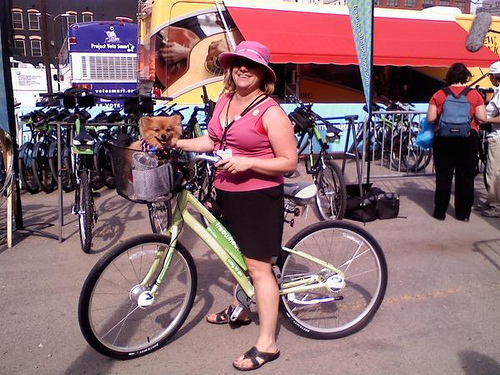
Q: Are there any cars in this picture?
A: No, there are no cars.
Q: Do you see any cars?
A: No, there are no cars.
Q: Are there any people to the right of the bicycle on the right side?
A: Yes, there is a person to the right of the bicycle.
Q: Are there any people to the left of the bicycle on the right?
A: No, the person is to the right of the bicycle.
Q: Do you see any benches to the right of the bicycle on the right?
A: No, there is a person to the right of the bicycle.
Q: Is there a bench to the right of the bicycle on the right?
A: No, there is a person to the right of the bicycle.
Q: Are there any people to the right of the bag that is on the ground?
A: Yes, there is a person to the right of the bag.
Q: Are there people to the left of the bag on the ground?
A: No, the person is to the right of the bag.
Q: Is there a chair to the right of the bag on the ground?
A: No, there is a person to the right of the bag.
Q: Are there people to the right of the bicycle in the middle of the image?
A: Yes, there is a person to the right of the bicycle.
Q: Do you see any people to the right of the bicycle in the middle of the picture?
A: Yes, there is a person to the right of the bicycle.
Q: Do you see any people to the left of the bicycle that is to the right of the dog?
A: No, the person is to the right of the bicycle.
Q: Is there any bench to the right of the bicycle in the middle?
A: No, there is a person to the right of the bicycle.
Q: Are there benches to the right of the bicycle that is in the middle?
A: No, there is a person to the right of the bicycle.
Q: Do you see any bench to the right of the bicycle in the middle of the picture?
A: No, there is a person to the right of the bicycle.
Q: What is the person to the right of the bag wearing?
A: The person is wearing a backpack.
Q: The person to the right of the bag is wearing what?
A: The person is wearing a backpack.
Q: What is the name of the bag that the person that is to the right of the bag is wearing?
A: The bag is a backpack.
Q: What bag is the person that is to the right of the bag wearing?
A: The person is wearing a backpack.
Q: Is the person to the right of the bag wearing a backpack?
A: Yes, the person is wearing a backpack.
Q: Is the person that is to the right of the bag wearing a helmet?
A: No, the person is wearing a backpack.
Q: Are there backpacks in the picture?
A: Yes, there is a backpack.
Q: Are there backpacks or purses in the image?
A: Yes, there is a backpack.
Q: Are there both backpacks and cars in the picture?
A: No, there is a backpack but no cars.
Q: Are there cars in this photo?
A: No, there are no cars.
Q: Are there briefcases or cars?
A: No, there are no cars or briefcases.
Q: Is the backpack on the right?
A: Yes, the backpack is on the right of the image.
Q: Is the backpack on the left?
A: No, the backpack is on the right of the image.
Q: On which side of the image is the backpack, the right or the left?
A: The backpack is on the right of the image.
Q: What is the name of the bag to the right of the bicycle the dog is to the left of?
A: The bag is a backpack.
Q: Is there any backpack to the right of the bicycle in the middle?
A: Yes, there is a backpack to the right of the bicycle.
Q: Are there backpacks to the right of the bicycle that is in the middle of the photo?
A: Yes, there is a backpack to the right of the bicycle.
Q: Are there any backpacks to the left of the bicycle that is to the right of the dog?
A: No, the backpack is to the right of the bicycle.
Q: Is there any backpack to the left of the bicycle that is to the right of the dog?
A: No, the backpack is to the right of the bicycle.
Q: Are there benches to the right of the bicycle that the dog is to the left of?
A: No, there is a backpack to the right of the bicycle.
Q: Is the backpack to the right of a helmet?
A: No, the backpack is to the right of a bicycle.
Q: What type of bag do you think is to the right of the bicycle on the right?
A: The bag is a backpack.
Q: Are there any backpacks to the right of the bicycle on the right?
A: Yes, there is a backpack to the right of the bicycle.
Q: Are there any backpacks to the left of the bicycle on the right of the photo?
A: No, the backpack is to the right of the bicycle.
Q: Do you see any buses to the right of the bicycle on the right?
A: No, there is a backpack to the right of the bicycle.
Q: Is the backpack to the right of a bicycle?
A: Yes, the backpack is to the right of a bicycle.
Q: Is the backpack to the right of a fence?
A: No, the backpack is to the right of a bicycle.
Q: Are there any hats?
A: Yes, there is a hat.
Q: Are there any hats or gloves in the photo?
A: Yes, there is a hat.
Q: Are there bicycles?
A: Yes, there is a bicycle.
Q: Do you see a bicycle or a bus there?
A: Yes, there is a bicycle.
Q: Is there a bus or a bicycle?
A: Yes, there is a bicycle.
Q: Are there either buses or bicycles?
A: Yes, there is a bicycle.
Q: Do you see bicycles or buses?
A: Yes, there is a bicycle.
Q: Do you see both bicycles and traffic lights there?
A: No, there is a bicycle but no traffic lights.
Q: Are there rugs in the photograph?
A: No, there are no rugs.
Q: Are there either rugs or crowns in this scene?
A: No, there are no rugs or crowns.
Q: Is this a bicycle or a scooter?
A: This is a bicycle.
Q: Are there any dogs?
A: Yes, there is a dog.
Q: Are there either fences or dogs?
A: Yes, there is a dog.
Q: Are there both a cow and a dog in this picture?
A: No, there is a dog but no cows.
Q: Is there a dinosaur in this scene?
A: No, there are no dinosaurs.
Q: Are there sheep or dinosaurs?
A: No, there are no dinosaurs or sheep.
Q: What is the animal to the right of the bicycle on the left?
A: The animal is a dog.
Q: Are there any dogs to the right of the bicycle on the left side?
A: Yes, there is a dog to the right of the bicycle.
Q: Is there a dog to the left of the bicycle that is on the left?
A: No, the dog is to the right of the bicycle.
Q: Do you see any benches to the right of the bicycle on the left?
A: No, there is a dog to the right of the bicycle.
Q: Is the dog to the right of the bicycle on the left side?
A: Yes, the dog is to the right of the bicycle.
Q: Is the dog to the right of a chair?
A: No, the dog is to the right of the bicycle.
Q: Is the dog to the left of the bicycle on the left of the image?
A: No, the dog is to the right of the bicycle.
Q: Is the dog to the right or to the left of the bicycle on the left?
A: The dog is to the right of the bicycle.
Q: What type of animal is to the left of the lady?
A: The animal is a dog.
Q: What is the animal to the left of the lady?
A: The animal is a dog.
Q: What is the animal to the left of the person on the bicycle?
A: The animal is a dog.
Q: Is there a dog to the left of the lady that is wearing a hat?
A: Yes, there is a dog to the left of the lady.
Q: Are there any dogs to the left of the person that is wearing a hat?
A: Yes, there is a dog to the left of the lady.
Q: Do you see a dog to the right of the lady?
A: No, the dog is to the left of the lady.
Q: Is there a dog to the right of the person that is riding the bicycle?
A: No, the dog is to the left of the lady.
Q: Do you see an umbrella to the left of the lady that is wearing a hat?
A: No, there is a dog to the left of the lady.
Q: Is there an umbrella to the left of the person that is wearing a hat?
A: No, there is a dog to the left of the lady.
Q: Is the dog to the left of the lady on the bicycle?
A: Yes, the dog is to the left of the lady.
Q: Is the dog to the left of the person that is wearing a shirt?
A: Yes, the dog is to the left of the lady.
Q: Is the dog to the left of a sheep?
A: No, the dog is to the left of the lady.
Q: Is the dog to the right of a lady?
A: No, the dog is to the left of a lady.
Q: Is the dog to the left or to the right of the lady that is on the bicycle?
A: The dog is to the left of the lady.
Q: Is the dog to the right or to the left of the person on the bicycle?
A: The dog is to the left of the lady.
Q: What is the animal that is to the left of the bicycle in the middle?
A: The animal is a dog.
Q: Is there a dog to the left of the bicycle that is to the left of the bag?
A: Yes, there is a dog to the left of the bicycle.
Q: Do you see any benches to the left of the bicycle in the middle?
A: No, there is a dog to the left of the bicycle.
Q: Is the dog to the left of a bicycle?
A: Yes, the dog is to the left of a bicycle.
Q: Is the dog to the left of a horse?
A: No, the dog is to the left of a bicycle.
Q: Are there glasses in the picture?
A: No, there are no glasses.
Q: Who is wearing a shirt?
A: The lady is wearing a shirt.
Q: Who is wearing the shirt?
A: The lady is wearing a shirt.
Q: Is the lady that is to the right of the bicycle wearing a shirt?
A: Yes, the lady is wearing a shirt.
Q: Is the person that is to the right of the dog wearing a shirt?
A: Yes, the lady is wearing a shirt.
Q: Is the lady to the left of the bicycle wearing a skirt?
A: No, the lady is wearing a shirt.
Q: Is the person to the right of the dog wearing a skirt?
A: No, the lady is wearing a shirt.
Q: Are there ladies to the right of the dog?
A: Yes, there is a lady to the right of the dog.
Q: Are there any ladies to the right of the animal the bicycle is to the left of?
A: Yes, there is a lady to the right of the dog.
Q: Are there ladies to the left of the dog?
A: No, the lady is to the right of the dog.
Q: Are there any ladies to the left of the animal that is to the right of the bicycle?
A: No, the lady is to the right of the dog.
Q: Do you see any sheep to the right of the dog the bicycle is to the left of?
A: No, there is a lady to the right of the dog.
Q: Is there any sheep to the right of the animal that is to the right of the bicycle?
A: No, there is a lady to the right of the dog.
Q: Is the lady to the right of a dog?
A: Yes, the lady is to the right of a dog.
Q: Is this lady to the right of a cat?
A: No, the lady is to the right of a dog.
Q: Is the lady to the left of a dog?
A: No, the lady is to the right of a dog.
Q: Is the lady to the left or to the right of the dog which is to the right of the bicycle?
A: The lady is to the right of the dog.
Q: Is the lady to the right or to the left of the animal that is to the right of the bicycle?
A: The lady is to the right of the dog.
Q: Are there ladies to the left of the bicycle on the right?
A: Yes, there is a lady to the left of the bicycle.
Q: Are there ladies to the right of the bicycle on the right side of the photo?
A: No, the lady is to the left of the bicycle.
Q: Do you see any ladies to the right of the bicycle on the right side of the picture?
A: No, the lady is to the left of the bicycle.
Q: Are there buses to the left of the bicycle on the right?
A: No, there is a lady to the left of the bicycle.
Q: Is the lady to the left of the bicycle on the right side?
A: Yes, the lady is to the left of the bicycle.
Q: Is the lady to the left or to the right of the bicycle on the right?
A: The lady is to the left of the bicycle.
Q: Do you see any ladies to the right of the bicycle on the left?
A: Yes, there is a lady to the right of the bicycle.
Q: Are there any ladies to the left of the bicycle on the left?
A: No, the lady is to the right of the bicycle.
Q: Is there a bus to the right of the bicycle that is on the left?
A: No, there is a lady to the right of the bicycle.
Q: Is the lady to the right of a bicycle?
A: Yes, the lady is to the right of a bicycle.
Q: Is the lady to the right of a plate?
A: No, the lady is to the right of a bicycle.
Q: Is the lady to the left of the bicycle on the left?
A: No, the lady is to the right of the bicycle.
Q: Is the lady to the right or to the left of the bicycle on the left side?
A: The lady is to the right of the bicycle.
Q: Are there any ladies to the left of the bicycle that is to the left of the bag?
A: Yes, there is a lady to the left of the bicycle.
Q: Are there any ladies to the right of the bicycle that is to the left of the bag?
A: No, the lady is to the left of the bicycle.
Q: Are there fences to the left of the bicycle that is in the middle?
A: No, there is a lady to the left of the bicycle.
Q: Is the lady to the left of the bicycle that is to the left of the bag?
A: Yes, the lady is to the left of the bicycle.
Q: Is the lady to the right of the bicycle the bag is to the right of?
A: No, the lady is to the left of the bicycle.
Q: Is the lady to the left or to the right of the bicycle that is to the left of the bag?
A: The lady is to the left of the bicycle.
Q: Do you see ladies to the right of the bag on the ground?
A: No, the lady is to the left of the bag.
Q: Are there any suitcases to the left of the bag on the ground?
A: No, there is a lady to the left of the bag.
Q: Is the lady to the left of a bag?
A: Yes, the lady is to the left of a bag.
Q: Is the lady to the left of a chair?
A: No, the lady is to the left of a bag.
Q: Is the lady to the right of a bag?
A: No, the lady is to the left of a bag.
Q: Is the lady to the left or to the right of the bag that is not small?
A: The lady is to the left of the bag.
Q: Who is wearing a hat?
A: The lady is wearing a hat.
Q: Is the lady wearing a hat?
A: Yes, the lady is wearing a hat.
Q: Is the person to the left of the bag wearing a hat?
A: Yes, the lady is wearing a hat.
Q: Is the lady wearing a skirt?
A: No, the lady is wearing a hat.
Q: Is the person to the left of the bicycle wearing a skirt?
A: No, the lady is wearing a hat.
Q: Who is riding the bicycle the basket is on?
A: The lady is riding the bicycle.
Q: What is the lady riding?
A: The lady is riding the bicycle.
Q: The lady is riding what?
A: The lady is riding the bicycle.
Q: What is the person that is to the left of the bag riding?
A: The lady is riding the bicycle.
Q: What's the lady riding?
A: The lady is riding the bicycle.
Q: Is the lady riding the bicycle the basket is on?
A: Yes, the lady is riding the bicycle.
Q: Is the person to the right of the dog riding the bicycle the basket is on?
A: Yes, the lady is riding the bicycle.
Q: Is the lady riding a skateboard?
A: No, the lady is riding the bicycle.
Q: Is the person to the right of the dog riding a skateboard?
A: No, the lady is riding the bicycle.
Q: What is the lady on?
A: The lady is on the bicycle.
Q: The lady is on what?
A: The lady is on the bicycle.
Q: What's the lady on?
A: The lady is on the bicycle.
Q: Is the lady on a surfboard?
A: No, the lady is on the bicycle.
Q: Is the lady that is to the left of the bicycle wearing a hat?
A: Yes, the lady is wearing a hat.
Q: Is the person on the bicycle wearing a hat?
A: Yes, the lady is wearing a hat.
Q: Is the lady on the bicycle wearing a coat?
A: No, the lady is wearing a hat.